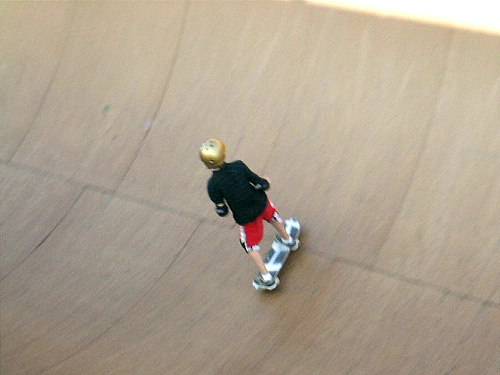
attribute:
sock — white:
[262, 266, 272, 284]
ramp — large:
[2, 2, 498, 373]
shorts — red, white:
[224, 197, 288, 259]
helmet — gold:
[179, 136, 230, 171]